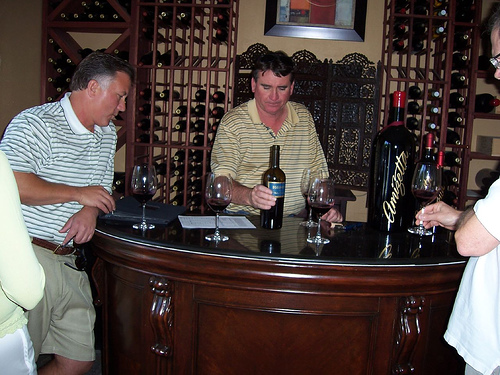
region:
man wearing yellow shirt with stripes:
[213, 54, 322, 209]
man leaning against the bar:
[16, 54, 118, 360]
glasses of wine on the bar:
[117, 158, 358, 254]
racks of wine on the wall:
[40, 2, 483, 212]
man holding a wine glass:
[409, 141, 498, 373]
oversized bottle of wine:
[362, 85, 419, 225]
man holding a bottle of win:
[208, 52, 342, 227]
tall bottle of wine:
[261, 143, 284, 228]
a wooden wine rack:
[140, 3, 234, 207]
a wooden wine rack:
[381, 0, 472, 212]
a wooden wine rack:
[38, 0, 138, 200]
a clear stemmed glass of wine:
[304, 176, 334, 246]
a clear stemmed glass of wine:
[201, 172, 234, 244]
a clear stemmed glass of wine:
[128, 164, 158, 231]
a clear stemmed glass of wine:
[406, 162, 441, 237]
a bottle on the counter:
[247, 123, 292, 227]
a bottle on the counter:
[374, 102, 394, 223]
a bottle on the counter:
[419, 123, 432, 214]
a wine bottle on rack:
[212, 87, 222, 98]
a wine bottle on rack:
[143, 87, 158, 99]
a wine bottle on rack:
[189, 116, 211, 143]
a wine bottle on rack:
[405, 23, 425, 49]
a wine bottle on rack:
[448, 91, 458, 103]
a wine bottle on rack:
[448, 112, 454, 130]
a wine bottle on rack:
[447, 151, 468, 176]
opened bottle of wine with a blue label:
[258, 143, 285, 233]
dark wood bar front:
[73, 225, 471, 372]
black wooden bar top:
[95, 198, 470, 266]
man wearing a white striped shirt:
[0, 45, 135, 372]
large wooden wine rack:
[145, 0, 242, 216]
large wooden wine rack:
[41, 0, 156, 203]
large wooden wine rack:
[366, 0, 473, 223]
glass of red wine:
[203, 166, 233, 245]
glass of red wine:
[128, 160, 158, 234]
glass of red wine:
[406, 157, 440, 235]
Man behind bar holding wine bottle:
[213, 46, 335, 235]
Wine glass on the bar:
[127, 162, 157, 234]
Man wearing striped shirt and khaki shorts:
[0, 78, 128, 372]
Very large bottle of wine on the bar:
[370, 88, 415, 242]